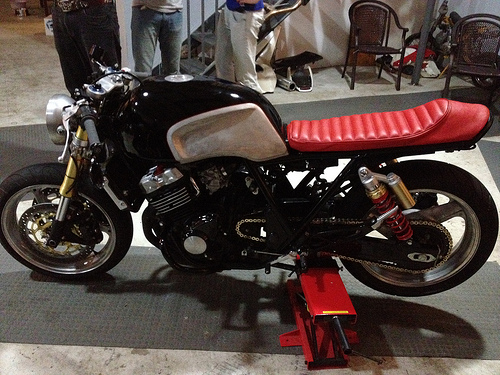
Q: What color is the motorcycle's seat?
A: Red.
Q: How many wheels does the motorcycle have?
A: Two.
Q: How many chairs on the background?
A: Two.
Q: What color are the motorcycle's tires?
A: Black.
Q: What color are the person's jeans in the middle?
A: Blue.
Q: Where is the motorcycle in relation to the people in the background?
A: In front of them.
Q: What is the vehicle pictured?
A: A motorcycle.